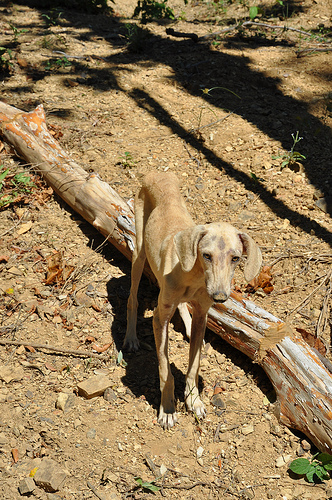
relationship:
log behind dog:
[0, 101, 331, 455] [121, 172, 261, 427]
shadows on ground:
[1, 1, 331, 418] [0, 0, 331, 499]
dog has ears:
[121, 172, 261, 427] [171, 222, 263, 282]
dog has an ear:
[121, 172, 261, 427] [173, 225, 209, 273]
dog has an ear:
[121, 172, 261, 427] [239, 233, 262, 281]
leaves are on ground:
[0, 0, 331, 499] [0, 0, 331, 499]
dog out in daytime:
[121, 172, 261, 427] [0, 0, 331, 500]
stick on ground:
[0, 338, 109, 362] [0, 0, 331, 499]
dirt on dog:
[212, 291, 227, 301] [121, 172, 261, 427]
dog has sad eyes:
[121, 172, 261, 427] [202, 252, 240, 262]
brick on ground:
[77, 374, 116, 398] [0, 0, 331, 499]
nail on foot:
[161, 424, 166, 432] [157, 401, 179, 431]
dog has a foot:
[121, 172, 261, 427] [157, 401, 179, 431]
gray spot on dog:
[217, 235, 226, 251] [121, 172, 261, 427]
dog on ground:
[121, 172, 261, 427] [0, 0, 331, 499]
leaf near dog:
[134, 478, 160, 493] [121, 172, 261, 427]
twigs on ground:
[0, 22, 331, 499] [0, 0, 331, 499]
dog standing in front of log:
[121, 172, 261, 427] [0, 101, 331, 455]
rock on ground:
[241, 426, 253, 435] [0, 0, 331, 499]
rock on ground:
[18, 477, 37, 495] [0, 0, 331, 499]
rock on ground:
[103, 387, 119, 402] [0, 0, 331, 499]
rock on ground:
[215, 353, 225, 363] [0, 0, 331, 499]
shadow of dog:
[107, 274, 204, 414] [121, 172, 261, 427]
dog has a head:
[121, 172, 261, 427] [174, 222, 262, 304]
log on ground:
[0, 101, 331, 455] [0, 0, 331, 499]